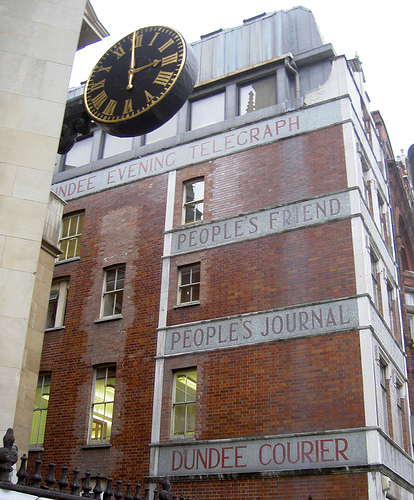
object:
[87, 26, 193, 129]
clock.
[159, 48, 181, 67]
roman numerals.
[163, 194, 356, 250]
wall writing.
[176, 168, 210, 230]
window.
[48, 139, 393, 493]
wall.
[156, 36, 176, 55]
roman numeral.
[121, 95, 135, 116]
numeral 6.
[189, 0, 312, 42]
roof.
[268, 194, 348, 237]
word.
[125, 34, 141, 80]
minute hand.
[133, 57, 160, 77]
hour hand.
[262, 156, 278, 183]
brick.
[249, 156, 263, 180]
red brick.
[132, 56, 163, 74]
pointy metal.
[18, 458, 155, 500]
pointy metal.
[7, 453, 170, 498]
metal fence.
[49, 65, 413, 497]
tall building.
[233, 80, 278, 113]
pane.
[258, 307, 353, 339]
journal.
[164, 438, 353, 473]
dundee courier.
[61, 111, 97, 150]
light hanging.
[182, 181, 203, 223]
shows reflection.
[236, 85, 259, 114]
shows reflections.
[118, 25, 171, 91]
it is 3.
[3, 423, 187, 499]
black gate.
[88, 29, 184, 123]
black face.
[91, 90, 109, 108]
gold numbers.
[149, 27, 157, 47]
clock number.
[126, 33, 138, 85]
gold hand.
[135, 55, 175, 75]
clock hand.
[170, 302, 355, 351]
people journal.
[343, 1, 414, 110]
sky.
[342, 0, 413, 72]
overcast sky.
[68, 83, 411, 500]
brick building.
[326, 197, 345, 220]
red letter.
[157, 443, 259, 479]
word dundee.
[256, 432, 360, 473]
word courier.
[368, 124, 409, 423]
side of building.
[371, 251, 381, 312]
long window.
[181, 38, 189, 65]
gold.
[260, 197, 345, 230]
friend.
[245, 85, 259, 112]
light.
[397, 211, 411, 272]
black balcony.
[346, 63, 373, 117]
gray side.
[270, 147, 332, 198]
multicolored brick.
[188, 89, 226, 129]
dark window.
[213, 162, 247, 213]
faded brick.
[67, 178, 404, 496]
brick wall.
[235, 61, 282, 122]
shiny top.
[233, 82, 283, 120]
window reflection.